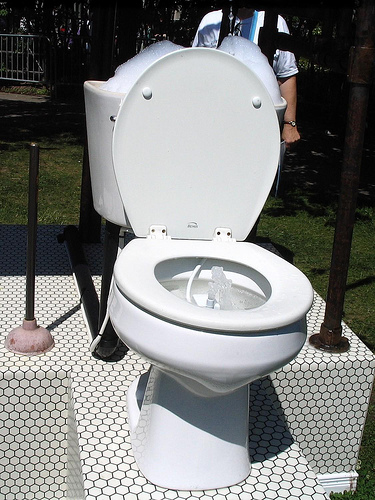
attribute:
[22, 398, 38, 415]
tile — tiny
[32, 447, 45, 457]
tile — tiny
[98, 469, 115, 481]
tile — tiny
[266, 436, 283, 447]
tile — tiny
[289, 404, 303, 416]
tile — tiny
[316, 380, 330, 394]
tile — tiny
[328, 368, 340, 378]
tile — tiny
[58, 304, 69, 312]
tile — tiny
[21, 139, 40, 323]
handle — black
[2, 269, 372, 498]
flooring — black and white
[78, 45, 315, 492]
toilet — white, displayed, clean, large, outdoor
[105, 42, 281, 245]
lid — white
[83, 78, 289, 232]
tank — white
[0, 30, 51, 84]
railing — silver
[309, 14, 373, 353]
pole — black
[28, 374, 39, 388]
tiles — tiny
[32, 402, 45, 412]
tiles — tiny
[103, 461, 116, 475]
tiles — tiny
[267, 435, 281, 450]
tiles — tiny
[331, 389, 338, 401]
tiles — tiny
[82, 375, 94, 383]
tiles — tiny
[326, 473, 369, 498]
weeds — small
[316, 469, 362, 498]
baseboard — white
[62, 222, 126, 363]
pipe — back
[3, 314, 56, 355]
plunger — long, toilet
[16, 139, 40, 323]
handle — black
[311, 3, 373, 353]
pipe — black , metal 